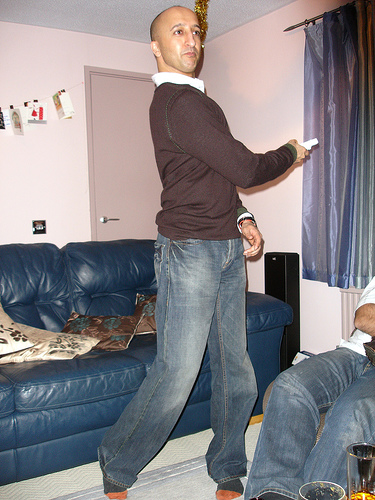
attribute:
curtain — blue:
[301, 5, 375, 289]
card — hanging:
[51, 88, 76, 121]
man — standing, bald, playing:
[96, 5, 313, 500]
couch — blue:
[0, 239, 294, 489]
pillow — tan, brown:
[61, 310, 144, 352]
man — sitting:
[244, 274, 375, 500]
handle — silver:
[98, 216, 121, 226]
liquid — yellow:
[347, 491, 375, 499]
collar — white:
[150, 72, 206, 94]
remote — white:
[298, 138, 318, 153]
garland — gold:
[196, 1, 207, 52]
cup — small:
[345, 443, 375, 500]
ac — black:
[264, 252, 302, 370]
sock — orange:
[216, 479, 244, 500]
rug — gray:
[2, 421, 263, 500]